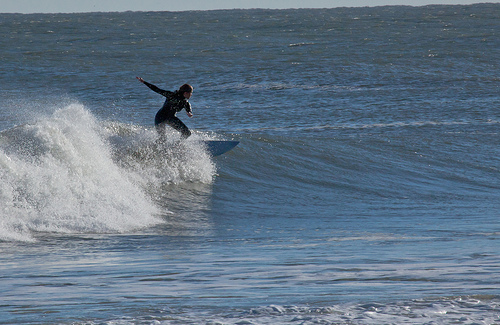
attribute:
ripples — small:
[33, 111, 283, 273]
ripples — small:
[60, 255, 148, 290]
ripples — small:
[172, 250, 452, 290]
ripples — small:
[308, 219, 483, 289]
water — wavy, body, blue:
[5, 10, 494, 324]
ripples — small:
[248, 188, 418, 262]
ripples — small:
[49, 257, 466, 293]